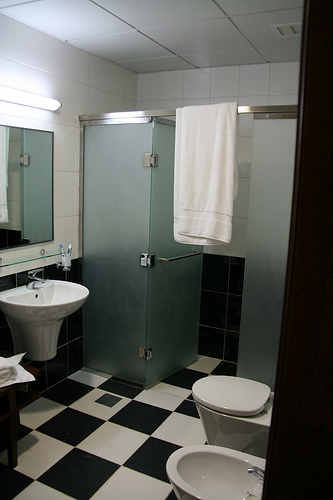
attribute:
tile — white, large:
[79, 423, 149, 468]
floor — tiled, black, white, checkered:
[1, 357, 242, 499]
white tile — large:
[0, 430, 73, 477]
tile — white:
[132, 382, 192, 411]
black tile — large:
[36, 407, 107, 450]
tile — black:
[38, 450, 120, 499]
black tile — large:
[109, 401, 171, 435]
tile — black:
[44, 381, 95, 408]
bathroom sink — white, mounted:
[1, 279, 89, 364]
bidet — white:
[167, 446, 266, 499]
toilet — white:
[191, 374, 273, 456]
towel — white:
[171, 105, 238, 250]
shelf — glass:
[0, 243, 69, 270]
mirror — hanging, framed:
[0, 126, 54, 249]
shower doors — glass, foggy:
[150, 125, 204, 384]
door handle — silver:
[157, 251, 204, 267]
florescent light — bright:
[4, 89, 60, 113]